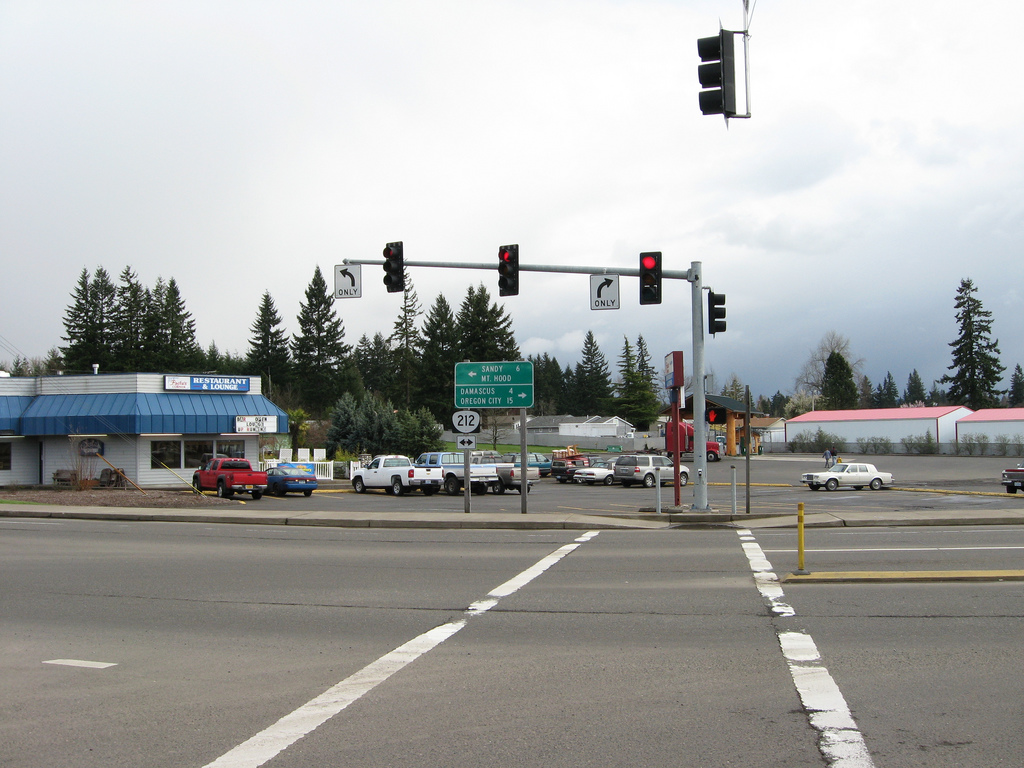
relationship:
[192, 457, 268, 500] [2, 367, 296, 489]
pickup truck in front of building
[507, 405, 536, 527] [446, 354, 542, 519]
post holding street sign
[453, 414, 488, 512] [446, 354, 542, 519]
post holding street sign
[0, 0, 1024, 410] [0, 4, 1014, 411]
sky in sky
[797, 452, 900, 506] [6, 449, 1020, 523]
white car parked on lot